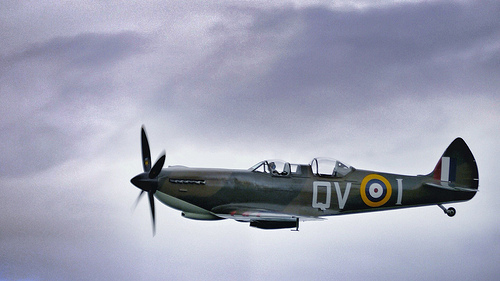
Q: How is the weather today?
A: It is cloudy.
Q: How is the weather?
A: It is cloudy.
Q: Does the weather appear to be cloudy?
A: Yes, it is cloudy.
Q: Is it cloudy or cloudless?
A: It is cloudy.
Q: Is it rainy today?
A: No, it is cloudy.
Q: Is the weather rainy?
A: No, it is cloudy.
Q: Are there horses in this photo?
A: No, there are no horses.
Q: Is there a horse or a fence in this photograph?
A: No, there are no horses or fences.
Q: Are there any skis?
A: No, there are no skis.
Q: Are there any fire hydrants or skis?
A: No, there are no skis or fire hydrants.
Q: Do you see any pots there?
A: No, there are no pots.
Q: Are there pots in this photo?
A: No, there are no pots.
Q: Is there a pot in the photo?
A: No, there are no pots.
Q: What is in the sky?
A: The clouds are in the sky.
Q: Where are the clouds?
A: The clouds are in the sky.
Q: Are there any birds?
A: No, there are no birds.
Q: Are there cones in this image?
A: No, there are no cones.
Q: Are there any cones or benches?
A: No, there are no cones or benches.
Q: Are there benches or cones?
A: No, there are no cones or benches.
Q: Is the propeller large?
A: Yes, the propeller is large.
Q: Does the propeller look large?
A: Yes, the propeller is large.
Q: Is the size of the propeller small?
A: No, the propeller is large.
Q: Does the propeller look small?
A: No, the propeller is large.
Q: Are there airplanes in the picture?
A: Yes, there is an airplane.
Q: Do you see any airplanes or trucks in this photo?
A: Yes, there is an airplane.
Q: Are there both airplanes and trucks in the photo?
A: No, there is an airplane but no trucks.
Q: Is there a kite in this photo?
A: No, there are no kites.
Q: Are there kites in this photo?
A: No, there are no kites.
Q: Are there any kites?
A: No, there are no kites.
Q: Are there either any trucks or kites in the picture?
A: No, there are no kites or trucks.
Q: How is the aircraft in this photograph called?
A: The aircraft is an airplane.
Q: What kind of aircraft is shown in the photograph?
A: The aircraft is an airplane.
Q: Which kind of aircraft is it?
A: The aircraft is an airplane.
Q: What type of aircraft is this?
A: This is an airplane.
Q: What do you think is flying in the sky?
A: The plane is flying in the sky.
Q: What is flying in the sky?
A: The plane is flying in the sky.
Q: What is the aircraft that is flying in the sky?
A: The aircraft is an airplane.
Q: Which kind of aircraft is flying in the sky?
A: The aircraft is an airplane.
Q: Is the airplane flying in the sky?
A: Yes, the airplane is flying in the sky.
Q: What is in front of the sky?
A: The airplane is in front of the sky.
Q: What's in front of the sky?
A: The airplane is in front of the sky.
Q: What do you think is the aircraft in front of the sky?
A: The aircraft is an airplane.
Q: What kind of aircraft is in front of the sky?
A: The aircraft is an airplane.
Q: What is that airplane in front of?
A: The airplane is in front of the sky.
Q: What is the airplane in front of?
A: The airplane is in front of the sky.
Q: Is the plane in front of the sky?
A: Yes, the plane is in front of the sky.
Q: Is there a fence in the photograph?
A: No, there are no fences.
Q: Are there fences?
A: No, there are no fences.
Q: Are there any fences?
A: No, there are no fences.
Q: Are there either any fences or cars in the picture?
A: No, there are no fences or cars.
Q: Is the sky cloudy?
A: Yes, the sky is cloudy.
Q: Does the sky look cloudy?
A: Yes, the sky is cloudy.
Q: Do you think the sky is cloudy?
A: Yes, the sky is cloudy.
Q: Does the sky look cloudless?
A: No, the sky is cloudy.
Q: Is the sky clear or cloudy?
A: The sky is cloudy.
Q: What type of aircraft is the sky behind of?
A: The sky is behind the plane.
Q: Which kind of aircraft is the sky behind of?
A: The sky is behind the plane.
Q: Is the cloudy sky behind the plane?
A: Yes, the sky is behind the plane.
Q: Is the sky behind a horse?
A: No, the sky is behind the plane.